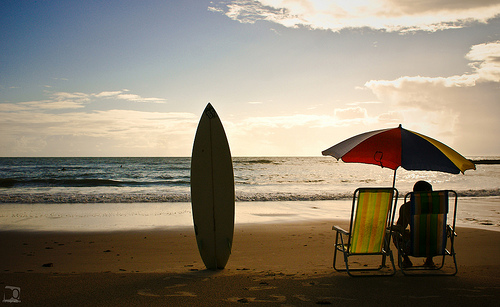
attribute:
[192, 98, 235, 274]
surfboard — tan, stuck, standing, vertical, standing vertically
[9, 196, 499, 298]
beach — sandy, tan, here, wave covered, brown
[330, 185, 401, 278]
chair — yellow, green, beach, sitting, multicolored, empty, here, orange, striped, beach chair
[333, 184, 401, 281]
beach chair — yellow, green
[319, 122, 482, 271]
umbrella — multi colored, open, yellow, red, colorful, big, white, blue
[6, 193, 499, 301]
sand — wet, brown, here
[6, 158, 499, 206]
waves — blue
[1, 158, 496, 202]
ocean — blue, white, filled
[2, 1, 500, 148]
clouds — white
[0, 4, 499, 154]
sky — blue, large, gray, cloudy, slightly cloudy, mostly blue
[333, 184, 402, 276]
metal — here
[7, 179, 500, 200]
wave — here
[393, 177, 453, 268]
person — sitting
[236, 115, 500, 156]
sun — setting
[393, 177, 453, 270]
hipster — here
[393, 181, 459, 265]
man — sitting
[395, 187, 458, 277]
chair — here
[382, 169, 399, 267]
pole — stuck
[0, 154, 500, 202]
ocean surf — beautiful, blue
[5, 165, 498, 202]
ocean waves — foamy, lapping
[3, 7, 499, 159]
line — horizon